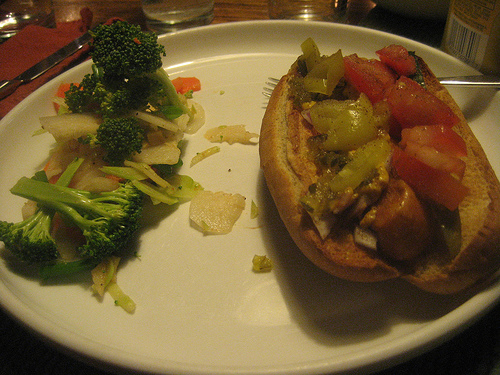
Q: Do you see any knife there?
A: Yes, there is a knife.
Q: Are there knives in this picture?
A: Yes, there is a knife.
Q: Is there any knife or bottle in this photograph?
A: Yes, there is a knife.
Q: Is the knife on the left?
A: Yes, the knife is on the left of the image.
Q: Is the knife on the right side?
A: No, the knife is on the left of the image.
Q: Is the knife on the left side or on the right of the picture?
A: The knife is on the left of the image.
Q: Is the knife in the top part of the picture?
A: Yes, the knife is in the top of the image.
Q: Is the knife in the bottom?
A: No, the knife is in the top of the image.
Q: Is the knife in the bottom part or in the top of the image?
A: The knife is in the top of the image.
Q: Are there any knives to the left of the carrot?
A: Yes, there is a knife to the left of the carrot.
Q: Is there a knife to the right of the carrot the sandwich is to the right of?
A: No, the knife is to the left of the carrot.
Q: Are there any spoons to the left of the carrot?
A: No, there is a knife to the left of the carrot.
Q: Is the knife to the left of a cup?
A: No, the knife is to the left of the carrot.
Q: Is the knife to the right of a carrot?
A: No, the knife is to the left of a carrot.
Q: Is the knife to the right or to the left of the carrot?
A: The knife is to the left of the carrot.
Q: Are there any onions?
A: Yes, there is an onion.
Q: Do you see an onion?
A: Yes, there is an onion.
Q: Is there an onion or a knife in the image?
A: Yes, there is an onion.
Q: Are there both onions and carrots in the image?
A: Yes, there are both an onion and a carrot.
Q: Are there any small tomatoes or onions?
A: Yes, there is a small onion.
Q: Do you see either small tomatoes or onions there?
A: Yes, there is a small onion.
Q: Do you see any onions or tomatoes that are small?
A: Yes, the onion is small.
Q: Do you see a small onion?
A: Yes, there is a small onion.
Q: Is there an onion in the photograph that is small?
A: Yes, there is an onion that is small.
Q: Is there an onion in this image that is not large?
A: Yes, there is a small onion.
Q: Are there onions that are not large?
A: Yes, there is a small onion.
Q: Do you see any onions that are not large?
A: Yes, there is a small onion.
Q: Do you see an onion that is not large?
A: Yes, there is a small onion.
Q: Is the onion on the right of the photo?
A: Yes, the onion is on the right of the image.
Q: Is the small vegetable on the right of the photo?
A: Yes, the onion is on the right of the image.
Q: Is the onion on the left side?
A: No, the onion is on the right of the image.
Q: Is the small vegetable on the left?
A: No, the onion is on the right of the image.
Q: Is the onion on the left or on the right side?
A: The onion is on the right of the image.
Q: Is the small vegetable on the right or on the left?
A: The onion is on the right of the image.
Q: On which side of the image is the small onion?
A: The onion is on the right of the image.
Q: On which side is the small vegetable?
A: The onion is on the right of the image.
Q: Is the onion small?
A: Yes, the onion is small.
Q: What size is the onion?
A: The onion is small.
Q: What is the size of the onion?
A: The onion is small.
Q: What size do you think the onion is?
A: The onion is small.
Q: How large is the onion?
A: The onion is small.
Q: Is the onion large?
A: No, the onion is small.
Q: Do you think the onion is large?
A: No, the onion is small.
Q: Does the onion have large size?
A: No, the onion is small.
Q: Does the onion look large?
A: No, the onion is small.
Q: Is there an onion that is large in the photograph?
A: No, there is an onion but it is small.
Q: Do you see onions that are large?
A: No, there is an onion but it is small.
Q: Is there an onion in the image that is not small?
A: No, there is an onion but it is small.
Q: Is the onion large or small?
A: The onion is small.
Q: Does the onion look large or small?
A: The onion is small.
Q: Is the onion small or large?
A: The onion is small.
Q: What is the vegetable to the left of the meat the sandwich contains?
A: The vegetable is an onion.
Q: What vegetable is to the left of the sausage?
A: The vegetable is an onion.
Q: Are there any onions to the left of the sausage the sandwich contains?
A: Yes, there is an onion to the left of the sausage.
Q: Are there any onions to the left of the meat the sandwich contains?
A: Yes, there is an onion to the left of the sausage.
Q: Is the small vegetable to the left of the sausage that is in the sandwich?
A: Yes, the onion is to the left of the sausage.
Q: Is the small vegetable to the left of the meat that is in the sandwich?
A: Yes, the onion is to the left of the sausage.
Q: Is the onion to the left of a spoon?
A: No, the onion is to the left of the sausage.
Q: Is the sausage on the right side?
A: Yes, the sausage is on the right of the image.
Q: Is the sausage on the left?
A: No, the sausage is on the right of the image.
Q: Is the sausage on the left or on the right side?
A: The sausage is on the right of the image.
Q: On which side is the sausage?
A: The sausage is on the right of the image.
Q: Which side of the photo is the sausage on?
A: The sausage is on the right of the image.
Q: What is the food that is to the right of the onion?
A: The food is a sausage.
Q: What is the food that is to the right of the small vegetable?
A: The food is a sausage.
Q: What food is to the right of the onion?
A: The food is a sausage.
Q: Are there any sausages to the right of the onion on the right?
A: Yes, there is a sausage to the right of the onion.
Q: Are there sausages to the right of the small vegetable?
A: Yes, there is a sausage to the right of the onion.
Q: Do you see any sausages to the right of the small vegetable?
A: Yes, there is a sausage to the right of the onion.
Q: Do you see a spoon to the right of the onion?
A: No, there is a sausage to the right of the onion.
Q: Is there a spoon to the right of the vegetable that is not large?
A: No, there is a sausage to the right of the onion.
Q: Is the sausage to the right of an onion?
A: Yes, the sausage is to the right of an onion.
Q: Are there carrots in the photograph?
A: Yes, there is a carrot.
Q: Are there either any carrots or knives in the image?
A: Yes, there is a carrot.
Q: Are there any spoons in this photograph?
A: No, there are no spoons.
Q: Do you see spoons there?
A: No, there are no spoons.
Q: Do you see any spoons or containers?
A: No, there are no spoons or containers.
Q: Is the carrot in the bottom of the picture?
A: No, the carrot is in the top of the image.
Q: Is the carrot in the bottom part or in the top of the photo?
A: The carrot is in the top of the image.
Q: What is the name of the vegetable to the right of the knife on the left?
A: The vegetable is a carrot.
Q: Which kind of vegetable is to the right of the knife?
A: The vegetable is a carrot.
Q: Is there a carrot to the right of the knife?
A: Yes, there is a carrot to the right of the knife.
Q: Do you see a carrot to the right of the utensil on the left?
A: Yes, there is a carrot to the right of the knife.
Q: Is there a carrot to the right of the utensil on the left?
A: Yes, there is a carrot to the right of the knife.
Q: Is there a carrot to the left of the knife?
A: No, the carrot is to the right of the knife.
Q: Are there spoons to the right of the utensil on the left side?
A: No, there is a carrot to the right of the knife.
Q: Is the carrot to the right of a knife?
A: Yes, the carrot is to the right of a knife.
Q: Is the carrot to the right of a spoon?
A: No, the carrot is to the right of a knife.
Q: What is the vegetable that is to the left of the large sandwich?
A: The vegetable is a carrot.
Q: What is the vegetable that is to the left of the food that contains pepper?
A: The vegetable is a carrot.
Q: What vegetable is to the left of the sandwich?
A: The vegetable is a carrot.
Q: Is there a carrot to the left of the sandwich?
A: Yes, there is a carrot to the left of the sandwich.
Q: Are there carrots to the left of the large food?
A: Yes, there is a carrot to the left of the sandwich.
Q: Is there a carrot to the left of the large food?
A: Yes, there is a carrot to the left of the sandwich.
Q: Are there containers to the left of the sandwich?
A: No, there is a carrot to the left of the sandwich.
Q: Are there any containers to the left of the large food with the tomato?
A: No, there is a carrot to the left of the sandwich.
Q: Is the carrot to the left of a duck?
A: No, the carrot is to the left of the sandwich.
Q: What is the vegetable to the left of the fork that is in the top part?
A: The vegetable is a carrot.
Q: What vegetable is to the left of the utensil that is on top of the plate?
A: The vegetable is a carrot.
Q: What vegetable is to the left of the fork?
A: The vegetable is a carrot.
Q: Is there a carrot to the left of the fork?
A: Yes, there is a carrot to the left of the fork.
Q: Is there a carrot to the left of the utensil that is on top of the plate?
A: Yes, there is a carrot to the left of the fork.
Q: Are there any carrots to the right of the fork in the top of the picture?
A: No, the carrot is to the left of the fork.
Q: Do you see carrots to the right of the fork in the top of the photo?
A: No, the carrot is to the left of the fork.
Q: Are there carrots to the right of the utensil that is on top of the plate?
A: No, the carrot is to the left of the fork.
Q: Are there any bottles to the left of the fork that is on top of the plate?
A: No, there is a carrot to the left of the fork.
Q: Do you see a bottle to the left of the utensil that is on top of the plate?
A: No, there is a carrot to the left of the fork.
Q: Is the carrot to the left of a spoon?
A: No, the carrot is to the left of the fork.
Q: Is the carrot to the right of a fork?
A: No, the carrot is to the left of a fork.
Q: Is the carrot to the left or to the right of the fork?
A: The carrot is to the left of the fork.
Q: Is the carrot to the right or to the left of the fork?
A: The carrot is to the left of the fork.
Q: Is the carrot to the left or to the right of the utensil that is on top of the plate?
A: The carrot is to the left of the fork.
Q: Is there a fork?
A: Yes, there is a fork.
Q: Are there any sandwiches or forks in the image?
A: Yes, there is a fork.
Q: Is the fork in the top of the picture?
A: Yes, the fork is in the top of the image.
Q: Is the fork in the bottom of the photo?
A: No, the fork is in the top of the image.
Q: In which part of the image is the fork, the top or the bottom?
A: The fork is in the top of the image.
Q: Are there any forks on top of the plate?
A: Yes, there is a fork on top of the plate.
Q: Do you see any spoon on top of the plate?
A: No, there is a fork on top of the plate.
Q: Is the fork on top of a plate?
A: Yes, the fork is on top of a plate.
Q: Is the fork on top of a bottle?
A: No, the fork is on top of a plate.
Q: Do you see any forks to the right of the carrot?
A: Yes, there is a fork to the right of the carrot.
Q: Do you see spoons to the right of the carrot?
A: No, there is a fork to the right of the carrot.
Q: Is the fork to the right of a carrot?
A: Yes, the fork is to the right of a carrot.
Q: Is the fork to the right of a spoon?
A: No, the fork is to the right of a carrot.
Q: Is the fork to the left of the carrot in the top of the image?
A: No, the fork is to the right of the carrot.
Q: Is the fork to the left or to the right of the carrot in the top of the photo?
A: The fork is to the right of the carrot.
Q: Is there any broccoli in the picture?
A: Yes, there is broccoli.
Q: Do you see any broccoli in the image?
A: Yes, there is broccoli.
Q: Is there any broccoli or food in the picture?
A: Yes, there is broccoli.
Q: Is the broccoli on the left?
A: Yes, the broccoli is on the left of the image.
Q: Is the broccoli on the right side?
A: No, the broccoli is on the left of the image.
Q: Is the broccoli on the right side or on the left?
A: The broccoli is on the left of the image.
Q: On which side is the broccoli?
A: The broccoli is on the left of the image.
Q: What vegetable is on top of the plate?
A: The vegetable is broccoli.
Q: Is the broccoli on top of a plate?
A: Yes, the broccoli is on top of a plate.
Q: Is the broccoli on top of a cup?
A: No, the broccoli is on top of a plate.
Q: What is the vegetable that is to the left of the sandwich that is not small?
A: The vegetable is broccoli.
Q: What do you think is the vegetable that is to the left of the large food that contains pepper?
A: The vegetable is broccoli.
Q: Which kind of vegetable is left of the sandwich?
A: The vegetable is broccoli.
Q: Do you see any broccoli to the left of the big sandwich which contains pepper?
A: Yes, there is broccoli to the left of the sandwich.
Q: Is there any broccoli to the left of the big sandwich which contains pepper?
A: Yes, there is broccoli to the left of the sandwich.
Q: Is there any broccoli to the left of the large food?
A: Yes, there is broccoli to the left of the sandwich.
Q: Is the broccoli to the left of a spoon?
A: No, the broccoli is to the left of a sandwich.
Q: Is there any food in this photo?
A: Yes, there is food.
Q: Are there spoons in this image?
A: No, there are no spoons.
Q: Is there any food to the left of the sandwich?
A: Yes, there is food to the left of the sandwich.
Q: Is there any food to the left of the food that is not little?
A: Yes, there is food to the left of the sandwich.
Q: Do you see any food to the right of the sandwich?
A: No, the food is to the left of the sandwich.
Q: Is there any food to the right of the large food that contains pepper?
A: No, the food is to the left of the sandwich.